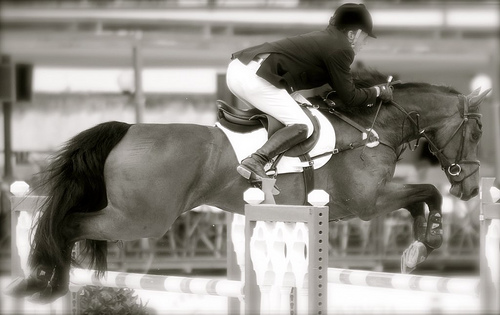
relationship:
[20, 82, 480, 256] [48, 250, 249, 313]
horse must clear th bar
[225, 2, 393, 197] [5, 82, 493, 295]
jockey riding horse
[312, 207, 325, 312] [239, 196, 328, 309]
holes on box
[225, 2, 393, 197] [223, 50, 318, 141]
jockey wears pants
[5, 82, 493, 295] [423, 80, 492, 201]
horse wears bridle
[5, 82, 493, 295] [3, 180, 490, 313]
horse over obstacle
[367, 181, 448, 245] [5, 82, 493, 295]
leg of horse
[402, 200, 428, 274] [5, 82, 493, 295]
leg of horse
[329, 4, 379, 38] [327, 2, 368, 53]
hat on head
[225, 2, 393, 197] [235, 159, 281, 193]
jockey wearing shoe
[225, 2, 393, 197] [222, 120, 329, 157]
jockey wearing shoes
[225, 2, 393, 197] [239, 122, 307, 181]
jockey wearing shoes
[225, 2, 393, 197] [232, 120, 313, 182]
jockey wearing boots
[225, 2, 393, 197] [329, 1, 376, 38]
jockey wearing hat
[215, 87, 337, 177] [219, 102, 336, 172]
pad under saddle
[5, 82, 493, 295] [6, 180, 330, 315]
horse jumping hurdle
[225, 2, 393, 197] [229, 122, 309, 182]
jockey wearing boots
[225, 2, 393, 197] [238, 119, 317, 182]
jockey wearing boots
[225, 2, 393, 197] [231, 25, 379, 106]
jockey wearing a coat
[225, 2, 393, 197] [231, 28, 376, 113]
jockey wearing a coat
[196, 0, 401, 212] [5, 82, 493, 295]
jockey riding horse